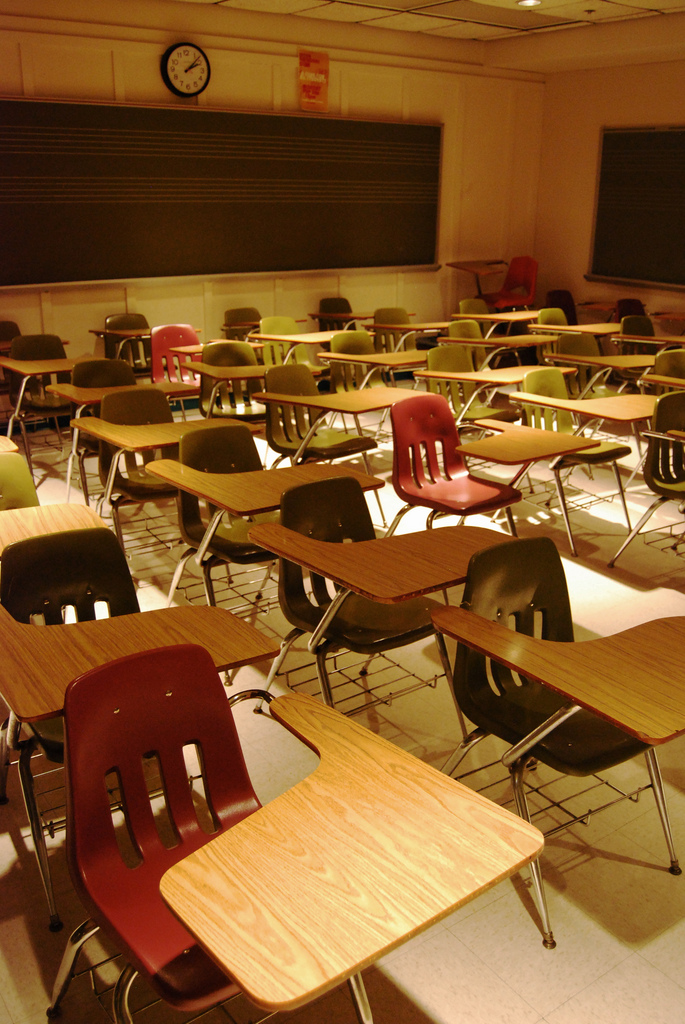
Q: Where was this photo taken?
A: School room.